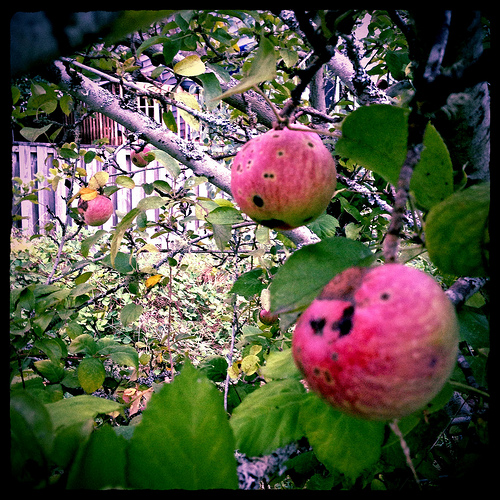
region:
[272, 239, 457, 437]
red fruit hanging from a tree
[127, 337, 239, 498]
healthy green leaf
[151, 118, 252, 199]
brown branch off of the tree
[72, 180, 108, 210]
yellow leaf on the tree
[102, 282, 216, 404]
green red and orange vegetation on the ground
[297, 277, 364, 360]
black holes in the fruit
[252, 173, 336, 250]
green part of a red fruit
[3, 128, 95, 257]
wooden fence by the trees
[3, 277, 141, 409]
small pile of green leaves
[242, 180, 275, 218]
rotten hole in the fruit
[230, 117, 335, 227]
Pink fruit on branch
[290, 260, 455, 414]
Pink fruit on branch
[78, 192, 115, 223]
Pink fruit on branch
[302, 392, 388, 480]
Small green leaf near pink fruit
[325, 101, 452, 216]
Small green leaf near pink fruit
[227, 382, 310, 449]
Small green leaf near pink fruit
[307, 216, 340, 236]
Small green leaf near pink fruit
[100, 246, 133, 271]
Large green leaf on tree branch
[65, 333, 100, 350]
Large green leaf on tree branch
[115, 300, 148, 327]
Large green leaf on tree branch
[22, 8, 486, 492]
a tree with fruits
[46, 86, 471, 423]
fruits in a tree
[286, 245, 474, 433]
fruit is pink and green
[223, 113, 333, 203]
part of the fruit that is pink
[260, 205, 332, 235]
part of the fruit that is green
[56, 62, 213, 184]
a big branch of a tree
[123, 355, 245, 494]
a leave of tree is green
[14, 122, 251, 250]
a fence behind a tree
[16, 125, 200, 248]
fence is made of wood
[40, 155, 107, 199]
yellow leaves in a tree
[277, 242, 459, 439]
red fruit on a tree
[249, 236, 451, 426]
fruit with black dots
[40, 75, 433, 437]
tree with apples on it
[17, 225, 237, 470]
the leaves are green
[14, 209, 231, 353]
bushes all around the tree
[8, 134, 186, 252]
fence in the background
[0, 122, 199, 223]
the fence is white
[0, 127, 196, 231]
the fence is made of wood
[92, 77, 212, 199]
the tree branch is grey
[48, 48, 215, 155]
a house behind the fence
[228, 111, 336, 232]
Pink fruit attached to branch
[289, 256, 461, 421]
Pink fruit attached to branch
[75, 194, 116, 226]
Pink fruit attached to branch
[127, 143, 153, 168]
Pink fruit attached to branch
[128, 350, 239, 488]
Green leaf near pink fruit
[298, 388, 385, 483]
Green leaf near pink fruit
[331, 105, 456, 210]
Green leaf near pink fruit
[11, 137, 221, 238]
Wooden brown fence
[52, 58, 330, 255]
Large brown tree branch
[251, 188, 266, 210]
Round small black spot on pink fruit